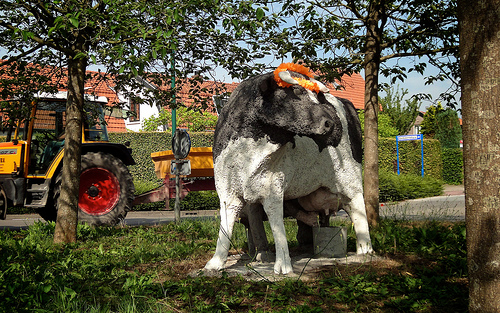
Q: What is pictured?
A: The statue of a cow.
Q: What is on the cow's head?
A: A wreath of flowers.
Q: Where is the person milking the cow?
A: Seated next to the cow.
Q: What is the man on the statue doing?
A: Pulling an utter.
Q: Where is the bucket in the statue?
A: Under the cow.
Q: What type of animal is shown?
A: Cow.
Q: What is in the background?
A: Building.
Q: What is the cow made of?
A: Concrete.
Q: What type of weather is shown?
A: Clear.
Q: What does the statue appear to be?
A: Cow.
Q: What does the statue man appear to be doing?
A: Milking the cow.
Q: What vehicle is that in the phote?
A: Tractor.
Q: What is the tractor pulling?
A: Trailer.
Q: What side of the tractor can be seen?
A: Left.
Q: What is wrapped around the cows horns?
A: Orange lei.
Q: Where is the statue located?
A: Between the trees.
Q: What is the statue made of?
A: Cement.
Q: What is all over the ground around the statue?
A: Grass and weeds.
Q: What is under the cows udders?
A: Bucket.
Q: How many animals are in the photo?
A: One.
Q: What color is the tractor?
A: Yellow.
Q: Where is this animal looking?
A: At the tree.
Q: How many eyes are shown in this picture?
A: One.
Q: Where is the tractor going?
A: Down the road.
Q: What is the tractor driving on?
A: A road.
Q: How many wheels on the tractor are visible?
A: One.